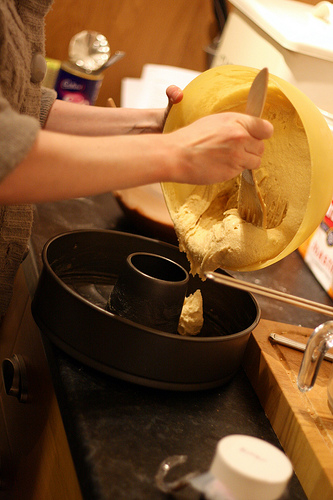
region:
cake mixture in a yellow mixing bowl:
[156, 61, 329, 277]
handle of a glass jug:
[293, 318, 332, 396]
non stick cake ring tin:
[24, 224, 263, 400]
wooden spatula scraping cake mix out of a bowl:
[232, 64, 277, 234]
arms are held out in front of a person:
[4, 78, 274, 206]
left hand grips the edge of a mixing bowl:
[149, 76, 191, 134]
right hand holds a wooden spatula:
[170, 68, 276, 230]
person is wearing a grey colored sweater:
[0, 1, 58, 318]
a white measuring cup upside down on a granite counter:
[191, 430, 293, 498]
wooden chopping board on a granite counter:
[246, 312, 331, 499]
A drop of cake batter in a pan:
[162, 269, 238, 341]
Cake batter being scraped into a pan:
[173, 113, 316, 276]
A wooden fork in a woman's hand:
[226, 58, 276, 224]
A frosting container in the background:
[51, 29, 120, 106]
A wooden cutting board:
[241, 309, 327, 389]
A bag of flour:
[288, 194, 327, 289]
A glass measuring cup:
[286, 308, 327, 422]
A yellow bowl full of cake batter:
[153, 62, 317, 271]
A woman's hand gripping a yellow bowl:
[156, 72, 234, 121]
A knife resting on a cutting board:
[264, 315, 324, 359]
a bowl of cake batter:
[124, 46, 331, 272]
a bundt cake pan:
[40, 219, 272, 391]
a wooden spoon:
[247, 57, 280, 247]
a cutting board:
[262, 280, 328, 465]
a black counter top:
[62, 374, 173, 492]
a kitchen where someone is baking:
[8, 2, 321, 382]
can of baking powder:
[51, 24, 114, 101]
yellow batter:
[175, 195, 246, 270]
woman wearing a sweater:
[3, 0, 63, 420]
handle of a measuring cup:
[295, 304, 330, 419]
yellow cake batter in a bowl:
[160, 67, 330, 272]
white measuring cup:
[196, 431, 313, 496]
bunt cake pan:
[31, 225, 264, 386]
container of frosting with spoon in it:
[51, 34, 117, 102]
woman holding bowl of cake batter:
[7, 33, 328, 269]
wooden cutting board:
[247, 314, 329, 491]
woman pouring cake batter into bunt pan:
[4, 15, 327, 315]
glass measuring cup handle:
[296, 315, 330, 394]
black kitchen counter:
[23, 355, 240, 496]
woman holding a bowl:
[43, 59, 327, 269]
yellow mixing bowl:
[143, 35, 332, 267]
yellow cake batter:
[178, 81, 311, 286]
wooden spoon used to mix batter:
[212, 69, 290, 237]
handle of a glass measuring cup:
[283, 298, 331, 395]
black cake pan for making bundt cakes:
[37, 206, 265, 398]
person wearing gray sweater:
[0, 3, 63, 205]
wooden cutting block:
[260, 300, 332, 496]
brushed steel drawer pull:
[2, 335, 43, 414]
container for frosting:
[43, 24, 128, 108]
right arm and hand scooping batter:
[0, 112, 291, 209]